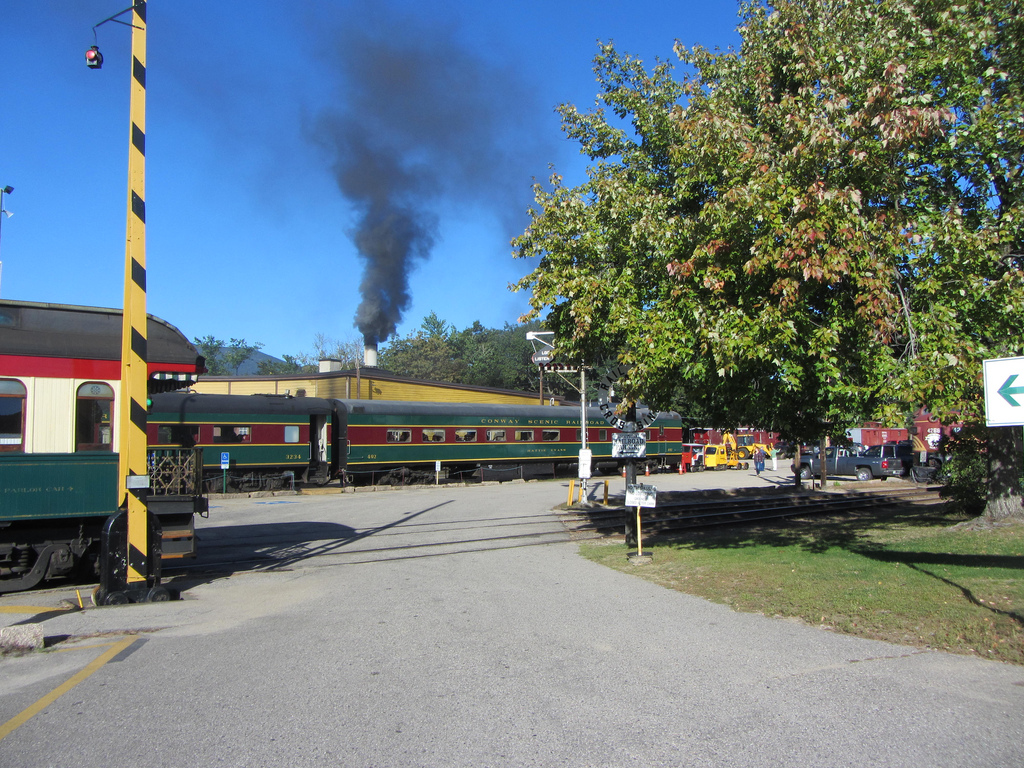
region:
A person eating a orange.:
[541, 251, 646, 441]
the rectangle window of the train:
[210, 423, 252, 444]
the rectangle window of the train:
[390, 426, 419, 439]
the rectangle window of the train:
[419, 423, 449, 442]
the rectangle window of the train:
[454, 424, 477, 443]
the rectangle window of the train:
[484, 427, 510, 443]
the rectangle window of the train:
[519, 428, 536, 444]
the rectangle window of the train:
[535, 424, 558, 438]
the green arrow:
[997, 374, 1021, 409]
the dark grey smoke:
[279, 22, 564, 345]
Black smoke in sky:
[309, 121, 449, 357]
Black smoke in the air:
[324, 152, 445, 353]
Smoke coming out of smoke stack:
[340, 152, 417, 359]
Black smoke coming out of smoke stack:
[325, 173, 430, 364]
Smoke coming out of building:
[324, 161, 436, 364]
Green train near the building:
[13, 315, 761, 499]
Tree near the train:
[550, 151, 1012, 526]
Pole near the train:
[520, 322, 603, 488]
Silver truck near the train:
[790, 436, 905, 490]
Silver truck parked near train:
[789, 442, 910, 487]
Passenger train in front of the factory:
[82, 332, 667, 567]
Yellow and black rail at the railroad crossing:
[15, 38, 313, 607]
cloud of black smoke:
[292, 11, 569, 348]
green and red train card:
[339, 395, 684, 484]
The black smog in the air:
[307, 9, 563, 343]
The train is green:
[144, 393, 770, 492]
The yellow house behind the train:
[196, 364, 570, 407]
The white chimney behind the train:
[359, 338, 380, 368]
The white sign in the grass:
[980, 354, 1022, 425]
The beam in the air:
[117, 3, 149, 592]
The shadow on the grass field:
[585, 486, 1020, 573]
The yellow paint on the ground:
[0, 629, 147, 735]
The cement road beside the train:
[0, 459, 1019, 766]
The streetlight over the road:
[525, 326, 595, 505]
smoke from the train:
[315, 250, 434, 343]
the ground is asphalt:
[471, 613, 548, 668]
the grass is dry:
[798, 576, 887, 634]